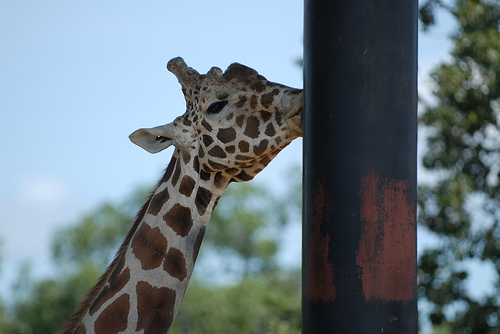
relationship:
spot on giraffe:
[161, 203, 197, 242] [64, 55, 303, 333]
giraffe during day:
[64, 55, 303, 333] [9, 32, 428, 298]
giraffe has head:
[64, 55, 303, 333] [177, 47, 296, 149]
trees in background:
[216, 209, 270, 241] [73, 179, 381, 317]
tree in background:
[427, 37, 494, 199] [0, 0, 499, 333]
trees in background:
[216, 209, 270, 241] [0, 0, 499, 333]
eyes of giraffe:
[195, 85, 283, 143] [64, 55, 303, 333]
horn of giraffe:
[165, 61, 227, 99] [64, 55, 303, 333]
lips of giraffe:
[283, 99, 312, 128] [64, 55, 303, 333]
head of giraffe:
[177, 47, 296, 149] [64, 55, 303, 333]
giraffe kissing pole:
[64, 55, 303, 333] [296, 12, 421, 322]